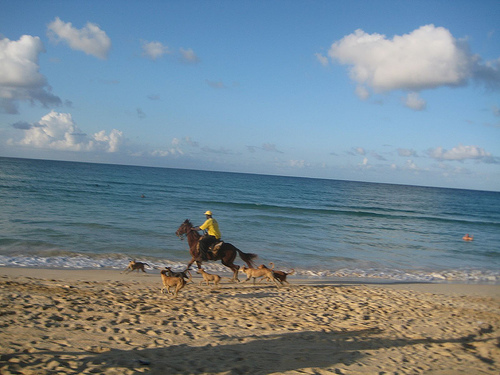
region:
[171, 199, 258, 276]
man riding horse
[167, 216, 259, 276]
horse on the beach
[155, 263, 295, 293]
dogs running on the beach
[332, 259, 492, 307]
waves meeting the ocean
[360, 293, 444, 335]
sand on the beach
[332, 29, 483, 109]
puffy clouds in the sky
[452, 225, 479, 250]
object in the ocean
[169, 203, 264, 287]
man riding a horse on the beach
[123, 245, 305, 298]
dogs running on the beach near the ocean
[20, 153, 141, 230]
ocean water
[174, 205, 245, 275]
a person riding a horse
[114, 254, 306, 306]
several dogs on the beach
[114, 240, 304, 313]
several dogs running with a horse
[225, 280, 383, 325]
tan sand of the beach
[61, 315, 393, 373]
shadow being cast on the sand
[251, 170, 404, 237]
calm blue waters of the ocean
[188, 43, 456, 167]
partly cloudy blue skies over the ocean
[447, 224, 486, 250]
person in the water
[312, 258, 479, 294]
tide water rolling onto the beach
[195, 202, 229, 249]
a man in a yellow shirt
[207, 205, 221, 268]
man on a horse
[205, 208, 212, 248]
man has a yellow shirt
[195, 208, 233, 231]
man has a yellow hat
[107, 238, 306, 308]
seven dogs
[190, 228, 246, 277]
horse is a deep brown color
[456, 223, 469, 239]
person in the water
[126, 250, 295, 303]
dogs running on the beach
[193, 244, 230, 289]
horse running on the beach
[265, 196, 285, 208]
small waves in the water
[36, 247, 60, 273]
water coming on shore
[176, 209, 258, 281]
rider galloping on the beach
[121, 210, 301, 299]
man riding a horse accompanied by a pack of dogs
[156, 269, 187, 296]
dog running on sand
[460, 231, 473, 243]
person swimming in the ocean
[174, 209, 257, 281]
man in yellow t-shirt riding a horse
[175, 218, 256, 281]
horse ridden by man wearing black pants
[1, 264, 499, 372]
beach sand with many footprints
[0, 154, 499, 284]
ocean with very small waves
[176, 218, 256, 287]
dog running on sand next to a horse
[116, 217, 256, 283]
dog running ahead of horse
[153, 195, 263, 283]
a man riding a horse on the beach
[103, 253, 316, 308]
a pack of dogs running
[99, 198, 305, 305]
dogs and a horse running on the beach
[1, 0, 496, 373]
a nice beach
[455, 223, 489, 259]
a man swimming in the ocean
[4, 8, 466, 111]
large clouds hovering over the ocean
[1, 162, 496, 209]
blue ocean water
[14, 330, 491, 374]
a shadow cast on the sand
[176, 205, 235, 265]
a man in a yellow shirt and hat riding a horse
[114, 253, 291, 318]
dogs running on the sandy beach